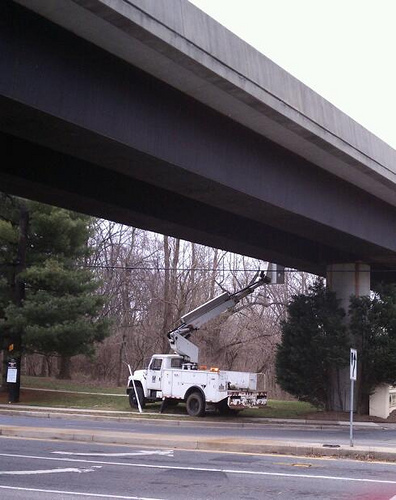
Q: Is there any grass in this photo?
A: Yes, there is grass.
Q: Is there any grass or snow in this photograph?
A: Yes, there is grass.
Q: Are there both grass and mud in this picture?
A: No, there is grass but no mud.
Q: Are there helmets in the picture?
A: No, there are no helmets.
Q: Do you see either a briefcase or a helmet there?
A: No, there are no helmets or briefcases.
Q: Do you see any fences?
A: No, there are no fences.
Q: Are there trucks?
A: Yes, there is a truck.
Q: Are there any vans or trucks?
A: Yes, there is a truck.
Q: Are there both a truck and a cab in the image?
A: No, there is a truck but no taxis.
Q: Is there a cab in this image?
A: No, there are no taxis.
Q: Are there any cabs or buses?
A: No, there are no cabs or buses.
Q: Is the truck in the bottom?
A: Yes, the truck is in the bottom of the image.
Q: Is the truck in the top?
A: No, the truck is in the bottom of the image.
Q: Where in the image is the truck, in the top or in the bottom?
A: The truck is in the bottom of the image.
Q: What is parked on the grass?
A: The truck is parked on the grass.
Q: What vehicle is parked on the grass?
A: The vehicle is a truck.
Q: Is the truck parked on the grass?
A: Yes, the truck is parked on the grass.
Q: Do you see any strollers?
A: No, there are no strollers.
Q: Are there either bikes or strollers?
A: No, there are no strollers or bikes.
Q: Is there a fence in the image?
A: No, there are no fences.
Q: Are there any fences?
A: No, there are no fences.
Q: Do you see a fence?
A: No, there are no fences.